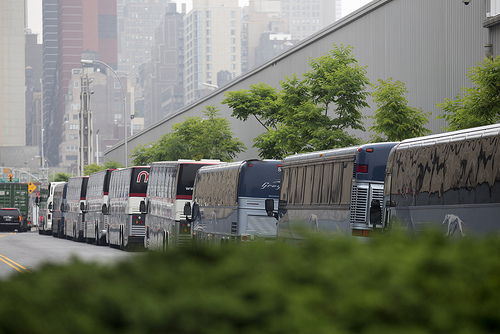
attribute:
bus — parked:
[262, 135, 399, 242]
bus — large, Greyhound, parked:
[51, 182, 64, 237]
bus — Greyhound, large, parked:
[60, 172, 89, 241]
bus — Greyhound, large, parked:
[79, 167, 127, 244]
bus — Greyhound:
[243, 154, 469, 252]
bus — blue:
[74, 120, 499, 291]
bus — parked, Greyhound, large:
[261, 105, 497, 272]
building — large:
[179, 10, 260, 87]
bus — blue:
[191, 158, 281, 257]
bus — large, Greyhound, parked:
[187, 156, 279, 248]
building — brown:
[0, 1, 32, 152]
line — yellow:
[1, 242, 39, 277]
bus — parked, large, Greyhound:
[93, 163, 167, 255]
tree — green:
[220, 44, 367, 159]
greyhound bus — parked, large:
[272, 144, 390, 247]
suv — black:
[0, 207, 22, 229]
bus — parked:
[182, 157, 280, 243]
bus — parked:
[139, 157, 216, 253]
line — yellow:
[66, 198, 156, 277]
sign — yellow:
[25, 183, 37, 193]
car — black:
[3, 208, 23, 225]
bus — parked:
[97, 165, 149, 248]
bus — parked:
[77, 166, 113, 246]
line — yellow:
[0, 253, 29, 274]